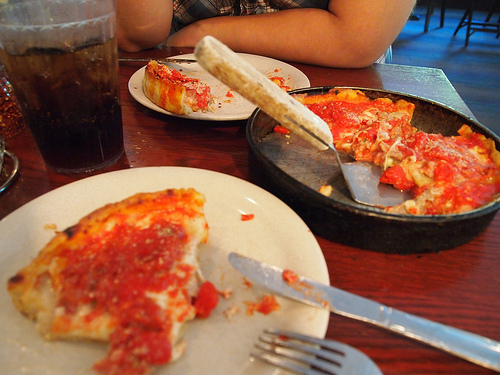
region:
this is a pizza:
[31, 187, 212, 367]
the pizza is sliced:
[25, 187, 223, 373]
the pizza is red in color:
[80, 210, 164, 316]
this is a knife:
[311, 290, 425, 321]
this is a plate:
[263, 209, 295, 253]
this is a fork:
[273, 330, 368, 373]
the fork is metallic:
[271, 342, 356, 373]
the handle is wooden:
[198, 38, 260, 92]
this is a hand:
[311, 3, 391, 58]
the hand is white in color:
[341, 0, 374, 55]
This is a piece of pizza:
[98, 302, 198, 372]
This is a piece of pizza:
[119, 187, 215, 246]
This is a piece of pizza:
[70, 223, 162, 307]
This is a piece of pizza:
[2, 247, 79, 337]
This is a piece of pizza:
[419, 120, 496, 201]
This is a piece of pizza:
[357, 92, 420, 174]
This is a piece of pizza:
[296, 88, 360, 135]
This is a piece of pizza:
[140, 45, 213, 132]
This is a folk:
[250, 319, 395, 370]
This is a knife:
[221, 232, 497, 338]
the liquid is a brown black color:
[27, 44, 82, 91]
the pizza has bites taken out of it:
[170, 203, 210, 361]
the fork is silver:
[241, 323, 343, 356]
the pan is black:
[353, 212, 398, 251]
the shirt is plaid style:
[181, 5, 208, 16]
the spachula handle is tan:
[186, 71, 327, 134]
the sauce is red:
[377, 163, 410, 193]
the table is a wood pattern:
[381, 262, 464, 297]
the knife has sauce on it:
[233, 239, 357, 324]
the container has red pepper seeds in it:
[3, 94, 26, 137]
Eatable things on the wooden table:
[13, 6, 498, 350]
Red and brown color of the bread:
[9, 183, 221, 366]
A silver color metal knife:
[231, 247, 423, 323]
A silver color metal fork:
[250, 329, 347, 374]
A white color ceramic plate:
[23, 180, 228, 370]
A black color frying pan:
[286, 87, 498, 204]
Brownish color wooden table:
[429, 257, 491, 314]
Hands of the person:
[131, 2, 391, 49]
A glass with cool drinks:
[8, 5, 128, 147]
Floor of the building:
[466, 63, 493, 96]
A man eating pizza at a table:
[0, 0, 497, 367]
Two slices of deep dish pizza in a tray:
[247, 75, 489, 227]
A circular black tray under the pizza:
[236, 66, 489, 253]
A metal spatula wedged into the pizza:
[192, 36, 412, 226]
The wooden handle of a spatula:
[187, 32, 335, 160]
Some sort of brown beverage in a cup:
[0, 12, 141, 182]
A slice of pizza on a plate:
[29, 198, 330, 373]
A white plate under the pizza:
[4, 152, 334, 372]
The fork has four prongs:
[254, 315, 346, 373]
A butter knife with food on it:
[227, 243, 499, 370]